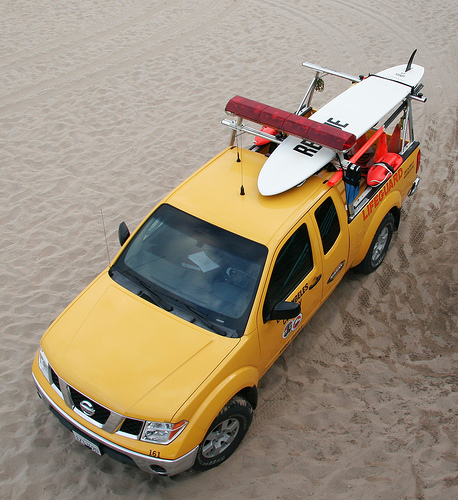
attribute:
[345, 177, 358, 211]
fins — blue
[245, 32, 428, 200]
surfboard — white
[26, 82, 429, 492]
truck — yellow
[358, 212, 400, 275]
tire — special 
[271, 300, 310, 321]
mirror — side-view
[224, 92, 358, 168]
light — red